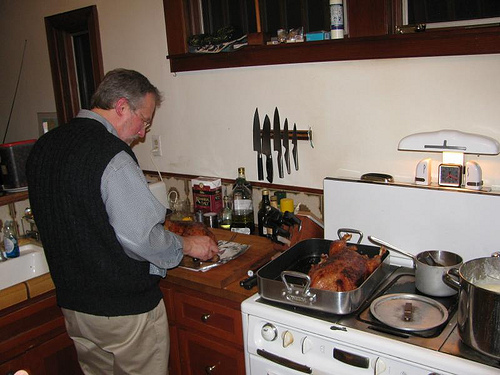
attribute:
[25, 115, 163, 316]
sweater — black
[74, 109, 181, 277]
shirt — gray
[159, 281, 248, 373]
cupboard — wood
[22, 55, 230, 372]
older man — cooking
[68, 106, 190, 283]
shirt — blue, oxford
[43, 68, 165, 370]
guy — wearing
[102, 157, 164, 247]
shirt — gray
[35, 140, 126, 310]
sweater — black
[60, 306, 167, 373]
pants — khaki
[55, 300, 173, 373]
pants — brown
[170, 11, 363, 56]
windows — dark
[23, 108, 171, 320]
sweater — black